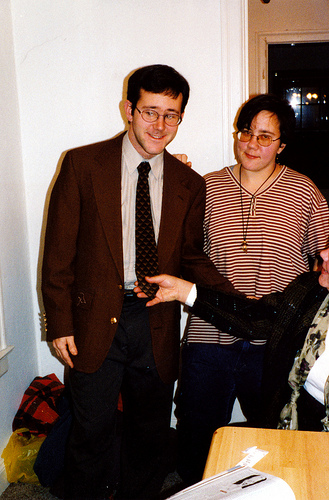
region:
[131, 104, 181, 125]
a pair of black rimmed glasses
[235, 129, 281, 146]
a pair of black rimmed glasses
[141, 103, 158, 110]
a dark eyebrow on a face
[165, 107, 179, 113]
a dark eyebrow on a face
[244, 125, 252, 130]
a dark eyebrow on a face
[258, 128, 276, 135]
a dark eyebrow on a face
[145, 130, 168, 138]
a mouth on a face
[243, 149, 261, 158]
a mouth on a face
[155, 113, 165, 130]
a nose on a face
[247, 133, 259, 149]
a nose on a face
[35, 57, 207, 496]
a person in the photo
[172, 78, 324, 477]
a person in the photo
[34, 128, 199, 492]
the man in a brown coat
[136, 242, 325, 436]
a person in the picture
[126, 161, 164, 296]
a black and brown tie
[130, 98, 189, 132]
the person is wearing glasses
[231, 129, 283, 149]
the person is wearing glasses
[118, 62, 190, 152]
the head of a person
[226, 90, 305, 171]
the head of a person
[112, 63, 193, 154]
the man has black hair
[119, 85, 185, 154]
A man is wearing glasses.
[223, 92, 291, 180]
A woman is wearing glasses.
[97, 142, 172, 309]
A tie's color is red and black.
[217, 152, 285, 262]
A woman is wearing a chain around her neck.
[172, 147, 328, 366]
A woman is wearing a striped shirt.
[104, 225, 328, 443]
A person is holding a man's tie.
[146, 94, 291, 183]
A woman has her hand on a man's shoulder.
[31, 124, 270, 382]
A man is wearing a red jacket.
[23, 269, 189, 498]
A man is wearing dark pants.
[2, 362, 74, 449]
A red and black object is in the background.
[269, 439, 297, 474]
part of a table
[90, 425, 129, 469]
part of a trouser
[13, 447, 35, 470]
part of a paperbag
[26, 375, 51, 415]
part of a showl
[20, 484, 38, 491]
part of a carpet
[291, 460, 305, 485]
part of a table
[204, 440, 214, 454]
edge of a table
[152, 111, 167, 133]
the nose of a man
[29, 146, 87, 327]
the arm of a man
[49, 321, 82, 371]
the hand of a man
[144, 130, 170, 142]
the mouth of a man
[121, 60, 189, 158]
the head of a man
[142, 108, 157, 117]
the eye of a man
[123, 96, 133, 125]
the ear of a man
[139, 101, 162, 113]
the eyebrow of a man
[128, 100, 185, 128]
a pair of glasses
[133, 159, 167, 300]
a neck tie